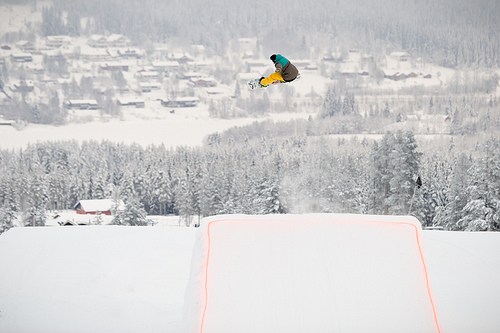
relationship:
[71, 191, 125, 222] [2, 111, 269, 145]
building in snow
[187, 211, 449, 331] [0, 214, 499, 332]
jump ramp in snow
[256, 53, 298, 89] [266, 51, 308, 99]
he in coat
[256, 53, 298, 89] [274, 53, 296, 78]
he in coat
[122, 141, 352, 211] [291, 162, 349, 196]
trees full of snow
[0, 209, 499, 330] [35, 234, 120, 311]
ground full of snow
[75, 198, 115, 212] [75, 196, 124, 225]
roof full of snow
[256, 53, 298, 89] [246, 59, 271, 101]
he jumps on snowboard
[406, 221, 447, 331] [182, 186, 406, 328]
line on ramp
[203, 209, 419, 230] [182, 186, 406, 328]
line on ramp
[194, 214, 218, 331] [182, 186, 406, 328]
line on ramp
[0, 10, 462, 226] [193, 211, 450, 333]
buildings below jump ramp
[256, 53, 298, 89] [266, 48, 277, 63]
he has hat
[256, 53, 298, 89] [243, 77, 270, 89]
he has snowboard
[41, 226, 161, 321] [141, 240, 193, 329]
snow covering ground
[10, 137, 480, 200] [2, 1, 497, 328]
trees covered with snow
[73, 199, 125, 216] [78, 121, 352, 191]
building surrounded by trees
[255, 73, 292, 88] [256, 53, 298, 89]
pants of he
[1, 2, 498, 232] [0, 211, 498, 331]
trees going down mountain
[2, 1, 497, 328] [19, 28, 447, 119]
snow on village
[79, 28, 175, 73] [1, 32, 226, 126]
houses on hill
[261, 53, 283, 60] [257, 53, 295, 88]
head of person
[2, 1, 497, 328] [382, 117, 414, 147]
snow on ground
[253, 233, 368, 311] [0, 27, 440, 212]
snow on houses